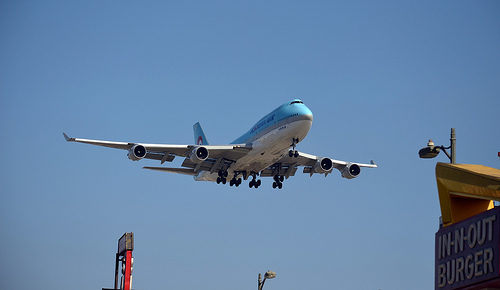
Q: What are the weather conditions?
A: It is clear.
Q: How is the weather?
A: It is clear.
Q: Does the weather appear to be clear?
A: Yes, it is clear.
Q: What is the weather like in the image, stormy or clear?
A: It is clear.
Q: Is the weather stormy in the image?
A: No, it is clear.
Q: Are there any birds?
A: No, there are no birds.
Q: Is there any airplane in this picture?
A: Yes, there is an airplane.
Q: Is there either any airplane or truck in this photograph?
A: Yes, there is an airplane.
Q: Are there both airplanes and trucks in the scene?
A: No, there is an airplane but no trucks.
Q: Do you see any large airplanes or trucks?
A: Yes, there is a large airplane.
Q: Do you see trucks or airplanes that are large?
A: Yes, the airplane is large.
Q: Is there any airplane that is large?
A: Yes, there is a large airplane.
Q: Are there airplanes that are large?
A: Yes, there is an airplane that is large.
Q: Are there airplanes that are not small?
A: Yes, there is a large airplane.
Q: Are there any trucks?
A: No, there are no trucks.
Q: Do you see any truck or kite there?
A: No, there are no trucks or kites.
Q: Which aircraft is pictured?
A: The aircraft is an airplane.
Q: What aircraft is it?
A: The aircraft is an airplane.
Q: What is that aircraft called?
A: This is an airplane.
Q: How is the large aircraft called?
A: The aircraft is an airplane.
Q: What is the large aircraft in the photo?
A: The aircraft is an airplane.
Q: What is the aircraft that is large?
A: The aircraft is an airplane.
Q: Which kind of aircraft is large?
A: The aircraft is an airplane.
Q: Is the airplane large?
A: Yes, the airplane is large.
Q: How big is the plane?
A: The plane is large.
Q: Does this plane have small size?
A: No, the plane is large.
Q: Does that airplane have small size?
A: No, the airplane is large.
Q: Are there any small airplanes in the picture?
A: No, there is an airplane but it is large.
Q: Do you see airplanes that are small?
A: No, there is an airplane but it is large.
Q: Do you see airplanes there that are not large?
A: No, there is an airplane but it is large.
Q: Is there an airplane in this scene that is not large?
A: No, there is an airplane but it is large.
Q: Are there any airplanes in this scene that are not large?
A: No, there is an airplane but it is large.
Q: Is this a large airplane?
A: Yes, this is a large airplane.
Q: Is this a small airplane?
A: No, this is a large airplane.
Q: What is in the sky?
A: The plane is in the sky.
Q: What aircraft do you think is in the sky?
A: The aircraft is an airplane.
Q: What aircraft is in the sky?
A: The aircraft is an airplane.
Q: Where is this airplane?
A: The airplane is in the sky.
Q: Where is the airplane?
A: The airplane is in the sky.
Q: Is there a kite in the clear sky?
A: No, there is an airplane in the sky.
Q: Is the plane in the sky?
A: Yes, the plane is in the sky.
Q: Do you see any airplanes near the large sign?
A: Yes, there is an airplane near the sign.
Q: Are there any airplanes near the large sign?
A: Yes, there is an airplane near the sign.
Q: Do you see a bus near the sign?
A: No, there is an airplane near the sign.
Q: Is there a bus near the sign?
A: No, there is an airplane near the sign.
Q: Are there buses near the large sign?
A: No, there is an airplane near the sign.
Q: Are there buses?
A: No, there are no buses.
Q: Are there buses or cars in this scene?
A: No, there are no buses or cars.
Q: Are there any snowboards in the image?
A: No, there are no snowboards.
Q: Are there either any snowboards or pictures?
A: No, there are no snowboards or pictures.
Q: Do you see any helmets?
A: No, there are no helmets.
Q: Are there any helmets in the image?
A: No, there are no helmets.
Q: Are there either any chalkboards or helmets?
A: No, there are no helmets or chalkboards.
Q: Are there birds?
A: No, there are no birds.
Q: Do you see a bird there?
A: No, there are no birds.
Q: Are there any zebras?
A: No, there are no zebras.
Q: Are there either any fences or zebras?
A: No, there are no zebras or fences.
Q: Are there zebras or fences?
A: No, there are no zebras or fences.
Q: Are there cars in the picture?
A: No, there are no cars.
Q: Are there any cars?
A: No, there are no cars.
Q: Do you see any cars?
A: No, there are no cars.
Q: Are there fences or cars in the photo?
A: No, there are no cars or fences.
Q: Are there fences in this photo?
A: No, there are no fences.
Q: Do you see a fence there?
A: No, there are no fences.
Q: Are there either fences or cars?
A: No, there are no fences or cars.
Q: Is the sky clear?
A: Yes, the sky is clear.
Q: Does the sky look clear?
A: Yes, the sky is clear.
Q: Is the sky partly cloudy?
A: No, the sky is clear.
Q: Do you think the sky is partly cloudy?
A: No, the sky is clear.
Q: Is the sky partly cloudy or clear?
A: The sky is clear.